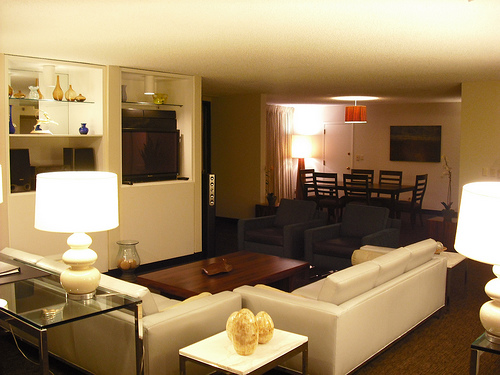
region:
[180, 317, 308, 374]
Table next to sofa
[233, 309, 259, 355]
Egg vase on table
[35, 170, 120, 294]
Lamp on glass table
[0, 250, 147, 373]
Glass table behind sofa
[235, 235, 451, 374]
Sofa is white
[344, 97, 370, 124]
Light above dining table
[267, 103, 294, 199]
Long white curtain by light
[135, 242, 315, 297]
Wooden table in front of sofa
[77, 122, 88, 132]
Small blue vase on shelf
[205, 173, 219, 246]
Floor speaker next to television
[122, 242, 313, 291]
the coffee table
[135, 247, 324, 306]
the coffee table is made of wood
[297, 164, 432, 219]
the dining room set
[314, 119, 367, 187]
the door is closed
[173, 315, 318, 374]
the end table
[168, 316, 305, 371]
the end table is black and white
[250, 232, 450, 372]
the sofa is made of leather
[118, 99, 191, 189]
the television in the home entertainment center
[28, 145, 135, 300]
the lamp on the table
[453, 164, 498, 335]
the lamp on the table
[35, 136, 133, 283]
lamp is bright white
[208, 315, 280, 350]
sculpture on white table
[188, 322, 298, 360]
white table between sofas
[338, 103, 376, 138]
red lamp on ceiling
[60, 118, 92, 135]
blue bottle on shelf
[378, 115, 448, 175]
black flat screen television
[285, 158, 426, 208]
numerous chairs at table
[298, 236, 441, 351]
sofa is off white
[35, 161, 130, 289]
white lamp on clear table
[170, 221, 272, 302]
brown table between sofas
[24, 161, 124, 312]
a lamp on a table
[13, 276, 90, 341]
a glass table top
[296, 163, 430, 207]
a dining room table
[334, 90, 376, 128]
a light hanging from the ceiling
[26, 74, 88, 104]
nick nacks on a shelf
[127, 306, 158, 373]
the leg of a table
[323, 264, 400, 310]
a cushion on a couch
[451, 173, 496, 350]
a lamp on a table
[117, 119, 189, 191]
a black television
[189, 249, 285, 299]
a brown coffee table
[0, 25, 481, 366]
A living room scene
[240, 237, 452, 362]
This is a couch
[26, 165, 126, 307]
A table lamp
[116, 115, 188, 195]
A television is sitting here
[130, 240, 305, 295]
This is a coffee table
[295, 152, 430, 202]
A dining room table and chairs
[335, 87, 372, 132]
A light is hanging from the ceiling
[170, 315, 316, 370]
This is an end table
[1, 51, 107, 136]
Shelves are built into the wall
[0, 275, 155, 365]
A glass table